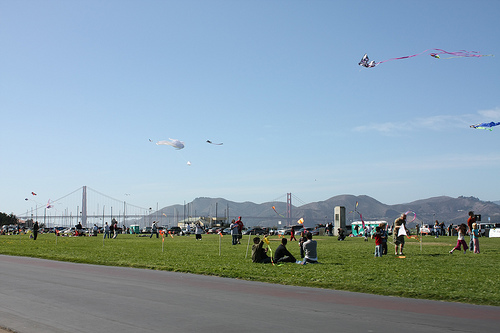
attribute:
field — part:
[287, 258, 387, 294]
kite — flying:
[163, 113, 275, 168]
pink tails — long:
[377, 43, 497, 70]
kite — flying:
[140, 136, 196, 169]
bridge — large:
[18, 186, 294, 226]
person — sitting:
[306, 233, 318, 261]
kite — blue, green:
[469, 118, 496, 130]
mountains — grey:
[135, 193, 499, 231]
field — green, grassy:
[344, 258, 496, 293]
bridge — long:
[7, 187, 386, 227]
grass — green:
[1, 227, 498, 305]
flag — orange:
[159, 229, 165, 253]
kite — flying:
[453, 115, 498, 160]